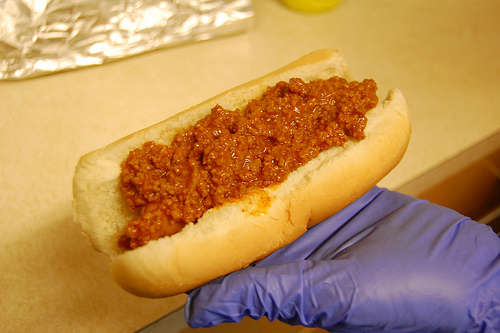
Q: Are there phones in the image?
A: No, there are no phones.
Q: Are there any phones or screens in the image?
A: No, there are no phones or screens.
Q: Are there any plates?
A: No, there are no plates.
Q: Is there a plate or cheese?
A: No, there are no plates or cheese.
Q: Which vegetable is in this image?
A: The vegetable is chili.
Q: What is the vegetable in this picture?
A: The vegetable is chili.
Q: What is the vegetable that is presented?
A: The vegetable is chili.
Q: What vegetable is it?
A: The vegetable is chili.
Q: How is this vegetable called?
A: This is chili.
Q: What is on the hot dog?
A: The chili is on the hot dog.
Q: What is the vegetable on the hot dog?
A: The vegetable is chili.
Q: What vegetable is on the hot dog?
A: The vegetable is chili.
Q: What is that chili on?
A: The chili is on the hot dog.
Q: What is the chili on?
A: The chili is on the hot dog.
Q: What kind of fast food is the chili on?
A: The chili is on the hot dog.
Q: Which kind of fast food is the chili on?
A: The chili is on the hot dog.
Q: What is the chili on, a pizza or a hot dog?
A: The chili is on a hot dog.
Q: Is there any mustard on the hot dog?
A: No, there is chili on the hot dog.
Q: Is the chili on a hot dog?
A: Yes, the chili is on a hot dog.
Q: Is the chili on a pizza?
A: No, the chili is on a hot dog.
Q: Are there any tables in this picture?
A: Yes, there is a table.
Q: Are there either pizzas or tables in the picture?
A: Yes, there is a table.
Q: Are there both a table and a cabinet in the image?
A: No, there is a table but no cabinets.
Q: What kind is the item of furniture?
A: The piece of furniture is a table.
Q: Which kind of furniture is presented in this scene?
A: The furniture is a table.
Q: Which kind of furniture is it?
A: The piece of furniture is a table.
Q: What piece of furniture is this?
A: This is a table.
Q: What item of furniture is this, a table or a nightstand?
A: This is a table.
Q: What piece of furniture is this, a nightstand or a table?
A: This is a table.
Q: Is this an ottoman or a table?
A: This is a table.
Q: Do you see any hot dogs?
A: Yes, there is a hot dog.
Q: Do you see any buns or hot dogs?
A: Yes, there is a hot dog.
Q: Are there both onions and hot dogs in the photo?
A: No, there is a hot dog but no onions.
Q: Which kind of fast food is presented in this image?
A: The fast food is a hot dog.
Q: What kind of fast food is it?
A: The food is a hot dog.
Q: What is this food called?
A: This is a hot dog.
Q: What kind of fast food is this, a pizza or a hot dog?
A: This is a hot dog.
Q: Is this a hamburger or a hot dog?
A: This is a hot dog.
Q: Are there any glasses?
A: No, there are no glasses.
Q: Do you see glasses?
A: No, there are no glasses.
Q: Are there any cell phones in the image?
A: No, there are no cell phones.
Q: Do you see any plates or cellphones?
A: No, there are no cellphones or plates.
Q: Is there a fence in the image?
A: No, there are no fences.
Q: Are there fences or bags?
A: No, there are no fences or bags.